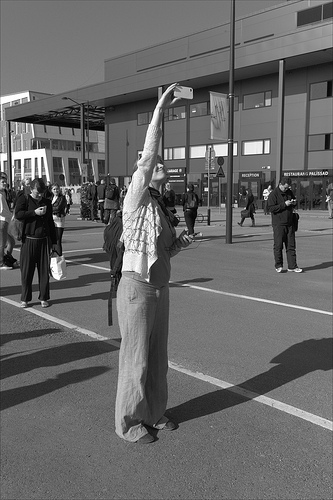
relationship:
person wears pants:
[113, 79, 188, 444] [116, 270, 177, 447]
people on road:
[75, 177, 120, 229] [68, 201, 332, 242]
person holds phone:
[113, 79, 188, 444] [171, 83, 196, 100]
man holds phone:
[267, 176, 305, 277] [288, 198, 298, 207]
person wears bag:
[236, 187, 257, 229] [239, 208, 254, 219]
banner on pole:
[208, 88, 232, 143] [226, 1, 234, 242]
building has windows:
[3, 2, 331, 207] [134, 91, 273, 162]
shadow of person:
[162, 336, 332, 425] [113, 79, 188, 444]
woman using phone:
[11, 176, 56, 310] [38, 204, 48, 215]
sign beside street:
[283, 169, 329, 178] [68, 201, 332, 242]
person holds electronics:
[113, 79, 188, 444] [182, 229, 205, 245]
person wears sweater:
[113, 79, 188, 444] [119, 122, 178, 283]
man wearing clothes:
[267, 176, 305, 277] [266, 188, 298, 270]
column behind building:
[85, 119, 91, 183] [3, 2, 331, 207]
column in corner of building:
[85, 119, 91, 183] [3, 2, 331, 207]